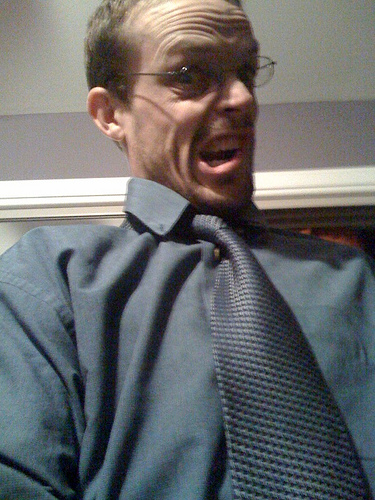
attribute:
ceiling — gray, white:
[2, 0, 374, 114]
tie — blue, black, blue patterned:
[189, 211, 374, 499]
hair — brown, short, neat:
[85, 0, 244, 153]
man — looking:
[2, 2, 373, 499]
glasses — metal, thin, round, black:
[97, 55, 279, 92]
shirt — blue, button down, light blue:
[2, 175, 374, 496]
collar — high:
[120, 175, 273, 239]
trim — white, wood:
[0, 162, 375, 225]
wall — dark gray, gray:
[0, 96, 375, 183]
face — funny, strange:
[128, 2, 258, 208]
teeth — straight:
[198, 134, 242, 155]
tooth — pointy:
[213, 138, 220, 155]